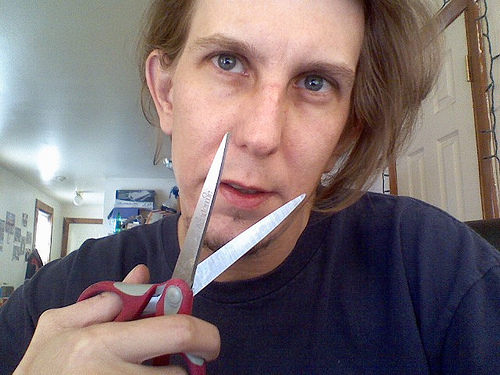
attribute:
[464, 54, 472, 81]
hinge — GOLD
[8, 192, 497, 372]
shirt — blue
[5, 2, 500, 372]
shirt — blue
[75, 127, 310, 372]
scissors — silver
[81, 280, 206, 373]
handle — gray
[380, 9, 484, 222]
door — white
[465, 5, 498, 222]
trim — brown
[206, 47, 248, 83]
eye — blue 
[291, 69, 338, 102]
eye — blue 